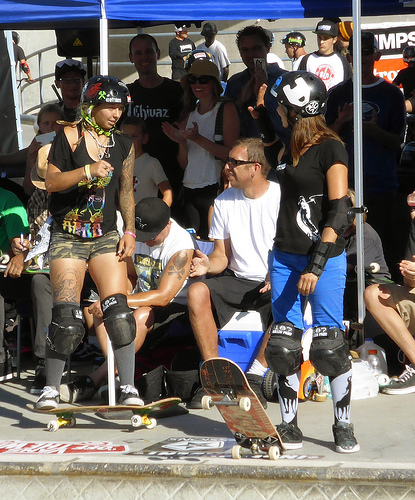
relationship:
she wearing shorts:
[37, 74, 147, 410] [34, 207, 141, 267]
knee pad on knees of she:
[100, 279, 154, 351] [37, 74, 147, 410]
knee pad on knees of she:
[37, 285, 89, 360] [37, 74, 147, 410]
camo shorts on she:
[48, 230, 124, 259] [37, 74, 147, 410]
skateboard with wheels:
[198, 355, 287, 456] [199, 388, 249, 414]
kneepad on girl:
[307, 327, 353, 378] [263, 71, 361, 454]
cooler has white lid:
[220, 329, 258, 363] [230, 310, 260, 327]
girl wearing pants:
[263, 71, 361, 454] [267, 243, 346, 335]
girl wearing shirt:
[263, 71, 361, 454] [272, 130, 347, 258]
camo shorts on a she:
[48, 230, 124, 263] [37, 74, 147, 410]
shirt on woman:
[252, 124, 332, 273] [54, 61, 180, 297]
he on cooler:
[217, 143, 334, 280] [195, 293, 287, 378]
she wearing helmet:
[37, 74, 147, 410] [76, 74, 131, 105]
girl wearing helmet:
[263, 71, 361, 454] [268, 68, 329, 113]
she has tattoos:
[84, 85, 128, 137] [118, 171, 131, 192]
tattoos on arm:
[118, 171, 131, 192] [119, 143, 135, 223]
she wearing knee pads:
[37, 74, 147, 410] [39, 303, 137, 343]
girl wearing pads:
[263, 71, 361, 454] [314, 192, 357, 248]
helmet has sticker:
[82, 72, 132, 104] [96, 88, 106, 99]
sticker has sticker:
[96, 88, 106, 99] [82, 80, 102, 100]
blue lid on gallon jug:
[365, 335, 373, 342] [354, 336, 388, 376]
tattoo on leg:
[51, 264, 80, 304] [35, 235, 85, 414]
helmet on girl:
[266, 68, 329, 118] [263, 71, 361, 454]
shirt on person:
[1, 188, 33, 255] [0, 155, 37, 386]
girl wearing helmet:
[251, 71, 351, 432] [271, 71, 323, 116]